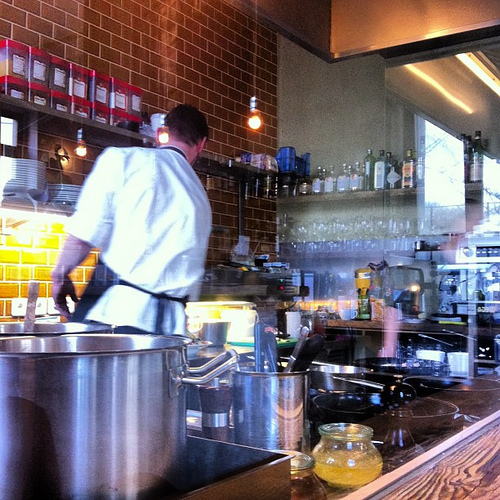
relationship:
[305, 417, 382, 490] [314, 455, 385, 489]
container with liquid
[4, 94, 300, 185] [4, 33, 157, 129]
shelf with spices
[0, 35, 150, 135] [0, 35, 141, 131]
containers with lids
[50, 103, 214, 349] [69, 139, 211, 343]
man in tshirt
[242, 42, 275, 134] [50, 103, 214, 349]
light hanging near man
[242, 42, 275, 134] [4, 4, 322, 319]
light hanging near wall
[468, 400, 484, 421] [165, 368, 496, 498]
part of table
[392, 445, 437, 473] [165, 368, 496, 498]
edge of table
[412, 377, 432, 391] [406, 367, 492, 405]
part of plate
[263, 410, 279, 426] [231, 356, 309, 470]
edge of tin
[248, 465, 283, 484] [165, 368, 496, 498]
part of table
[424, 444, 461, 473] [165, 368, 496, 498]
edge of table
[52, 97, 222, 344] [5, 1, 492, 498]
chef cooking in kitchen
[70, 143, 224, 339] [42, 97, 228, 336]
shirt on man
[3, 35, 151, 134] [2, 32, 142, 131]
containers of spices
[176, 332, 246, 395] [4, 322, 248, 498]
handle on pot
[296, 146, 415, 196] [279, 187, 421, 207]
bottle on shelf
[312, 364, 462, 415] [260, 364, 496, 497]
pans on counter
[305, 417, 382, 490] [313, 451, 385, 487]
container of liquid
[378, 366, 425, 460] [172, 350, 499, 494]
grinder on counter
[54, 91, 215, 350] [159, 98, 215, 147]
man with hair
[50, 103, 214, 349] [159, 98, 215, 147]
man with hair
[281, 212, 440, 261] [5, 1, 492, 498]
glasses in kitchen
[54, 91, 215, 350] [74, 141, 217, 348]
man in shirt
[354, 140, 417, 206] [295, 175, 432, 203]
bottle on shelf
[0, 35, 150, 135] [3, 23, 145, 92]
containers with lids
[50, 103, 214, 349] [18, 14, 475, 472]
man in restaurant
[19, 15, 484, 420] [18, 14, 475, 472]
area in restaurant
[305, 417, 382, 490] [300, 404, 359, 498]
container with liquid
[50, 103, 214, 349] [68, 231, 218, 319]
man wearing apron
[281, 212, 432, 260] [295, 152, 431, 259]
glasses on wall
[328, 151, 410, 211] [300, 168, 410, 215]
jars on shelf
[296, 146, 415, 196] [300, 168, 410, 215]
bottle on shelf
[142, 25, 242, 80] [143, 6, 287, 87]
wall made of bricks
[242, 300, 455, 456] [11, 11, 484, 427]
items in kitchen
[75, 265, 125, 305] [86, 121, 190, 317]
apron on man